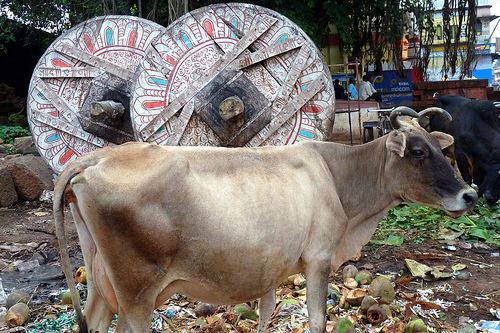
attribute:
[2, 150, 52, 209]
rock — big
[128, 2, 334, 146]
colorful wheel — large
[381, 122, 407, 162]
ear — light brown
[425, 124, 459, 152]
ear — light brown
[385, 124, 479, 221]
cow's face — black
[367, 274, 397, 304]
melon — broken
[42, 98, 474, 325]
cow — bony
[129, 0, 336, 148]
wheel — large, colorful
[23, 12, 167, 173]
wheel — large, colorful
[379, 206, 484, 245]
material — green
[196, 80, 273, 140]
center — black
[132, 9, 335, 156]
wheel — large